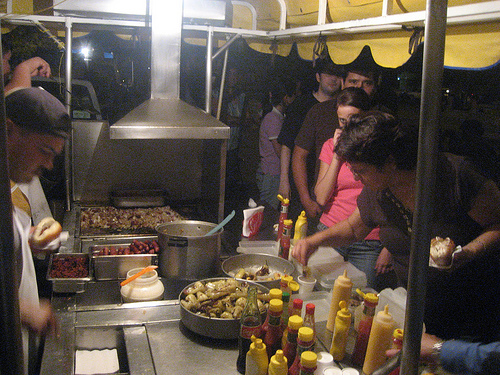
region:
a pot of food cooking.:
[173, 274, 288, 349]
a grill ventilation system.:
[106, 0, 236, 140]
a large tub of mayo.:
[113, 258, 173, 314]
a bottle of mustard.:
[290, 203, 320, 241]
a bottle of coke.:
[232, 276, 267, 372]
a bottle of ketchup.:
[259, 299, 284, 350]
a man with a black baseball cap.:
[4, 80, 81, 172]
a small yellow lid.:
[266, 292, 290, 312]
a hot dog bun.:
[34, 198, 69, 253]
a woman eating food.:
[281, 90, 414, 276]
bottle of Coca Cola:
[233, 282, 259, 372]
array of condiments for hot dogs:
[231, 272, 406, 372]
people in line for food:
[252, 57, 497, 302]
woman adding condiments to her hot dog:
[287, 104, 498, 311]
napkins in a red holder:
[237, 202, 267, 237]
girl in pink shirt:
[312, 85, 384, 280]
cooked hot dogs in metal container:
[85, 237, 160, 274]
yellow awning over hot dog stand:
[0, 2, 496, 77]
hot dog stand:
[0, 3, 386, 371]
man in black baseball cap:
[1, 88, 81, 374]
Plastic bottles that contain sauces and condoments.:
[288, 271, 397, 374]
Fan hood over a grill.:
[61, 18, 281, 145]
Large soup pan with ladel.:
[142, 214, 232, 282]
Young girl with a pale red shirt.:
[316, 89, 376, 241]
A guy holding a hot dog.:
[7, 71, 88, 292]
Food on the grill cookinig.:
[73, 183, 208, 245]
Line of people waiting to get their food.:
[215, 58, 340, 205]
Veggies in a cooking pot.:
[172, 273, 279, 335]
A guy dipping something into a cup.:
[280, 126, 427, 302]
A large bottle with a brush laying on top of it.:
[110, 263, 193, 305]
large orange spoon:
[111, 257, 156, 284]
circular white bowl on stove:
[110, 259, 170, 300]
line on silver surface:
[136, 317, 161, 373]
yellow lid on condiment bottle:
[242, 329, 282, 355]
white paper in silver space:
[73, 332, 118, 373]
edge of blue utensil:
[204, 201, 270, 226]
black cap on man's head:
[23, 92, 87, 152]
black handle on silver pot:
[153, 227, 205, 252]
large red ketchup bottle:
[263, 189, 291, 245]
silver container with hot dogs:
[88, 219, 175, 271]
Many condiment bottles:
[236, 269, 403, 374]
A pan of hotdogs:
[88, 240, 159, 276]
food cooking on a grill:
[78, 204, 189, 234]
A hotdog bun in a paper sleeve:
[29, 218, 68, 249]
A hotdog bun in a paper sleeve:
[428, 237, 463, 269]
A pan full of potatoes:
[178, 275, 277, 340]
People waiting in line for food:
[182, 58, 395, 286]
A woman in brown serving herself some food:
[291, 112, 499, 342]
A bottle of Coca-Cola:
[236, 286, 261, 369]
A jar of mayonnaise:
[118, 266, 165, 301]